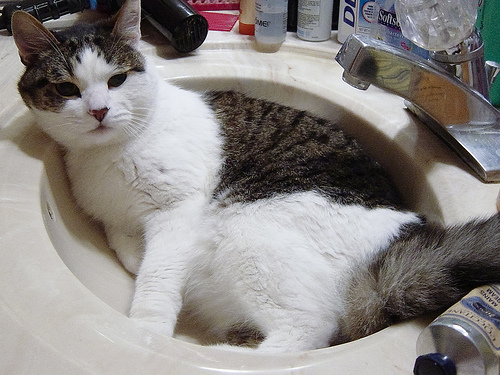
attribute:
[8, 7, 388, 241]
cat — white, awake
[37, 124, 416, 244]
sink — marble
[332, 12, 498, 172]
faucet — off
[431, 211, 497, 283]
tail — black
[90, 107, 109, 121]
nose — pink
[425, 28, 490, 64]
knob — clear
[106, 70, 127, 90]
eye — black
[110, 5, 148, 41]
ears — up